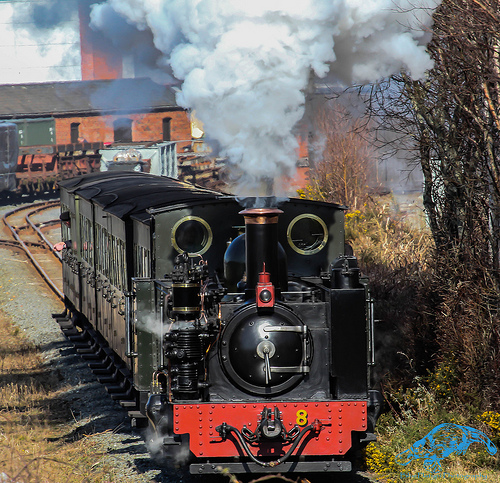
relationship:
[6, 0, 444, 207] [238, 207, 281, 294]
smoke coming out stack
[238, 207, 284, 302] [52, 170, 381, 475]
pipe on locomotive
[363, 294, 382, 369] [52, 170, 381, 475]
handle on locomotive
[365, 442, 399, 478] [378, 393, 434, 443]
leaves on ground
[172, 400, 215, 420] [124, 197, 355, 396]
bolts on front of train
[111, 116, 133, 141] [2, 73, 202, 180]
door in building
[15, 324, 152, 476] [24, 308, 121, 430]
shadow on ground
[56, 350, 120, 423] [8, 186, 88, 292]
gravel beside track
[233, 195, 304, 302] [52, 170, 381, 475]
pipe in front of locomotive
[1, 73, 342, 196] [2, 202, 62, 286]
building beside track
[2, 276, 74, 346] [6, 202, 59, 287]
gravel near tracks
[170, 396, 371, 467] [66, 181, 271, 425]
bumper of locomotive